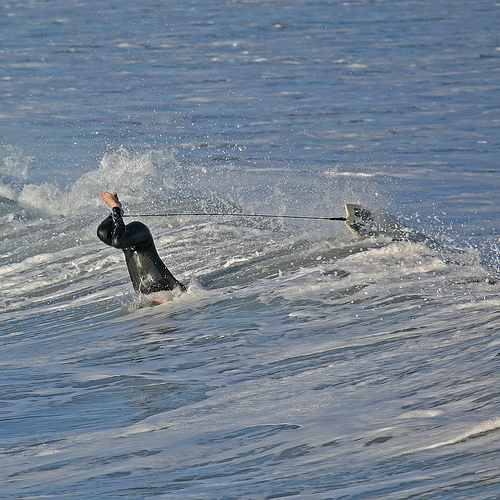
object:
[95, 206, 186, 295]
wetsuit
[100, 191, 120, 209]
foot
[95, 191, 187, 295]
person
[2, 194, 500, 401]
wave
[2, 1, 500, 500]
water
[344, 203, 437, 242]
surfboard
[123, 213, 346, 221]
cord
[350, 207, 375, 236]
design